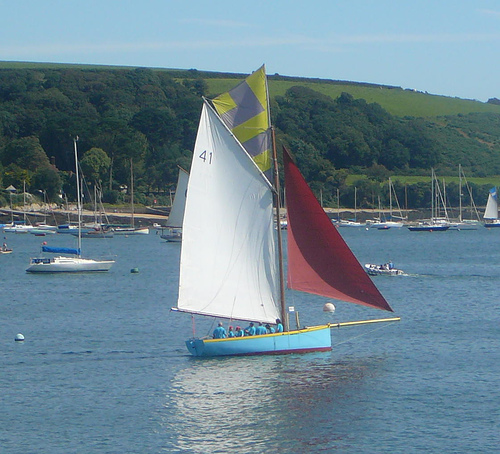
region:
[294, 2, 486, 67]
this is the sky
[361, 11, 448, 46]
the sky is blue in color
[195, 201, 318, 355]
this is a boat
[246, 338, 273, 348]
the boat is blue in color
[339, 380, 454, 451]
this is a water body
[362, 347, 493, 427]
the water is calm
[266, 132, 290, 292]
this is a pole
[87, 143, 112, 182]
this is a tree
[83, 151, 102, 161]
the leaves are green in color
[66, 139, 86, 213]
the pole is white in color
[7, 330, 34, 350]
small white buoy in water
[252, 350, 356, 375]
boat's blue reflection on water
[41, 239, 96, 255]
blue mast on boat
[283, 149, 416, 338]
red sail at end of boat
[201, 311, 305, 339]
people sitting in boat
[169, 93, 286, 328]
tall white mast on pole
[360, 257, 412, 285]
people in speed boat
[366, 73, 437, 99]
houses on the mountain top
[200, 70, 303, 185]
yellow and gray flag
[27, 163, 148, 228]
houses on the shore line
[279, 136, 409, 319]
A red sail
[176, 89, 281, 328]
A white sail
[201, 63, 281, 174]
A yellow and grey sail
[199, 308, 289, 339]
A group of people on a boat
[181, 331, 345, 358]
A blue boat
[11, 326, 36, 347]
A white bobber in the water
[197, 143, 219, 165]
The number 41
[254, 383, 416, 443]
Small ripples in the water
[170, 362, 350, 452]
The sailboat's reflection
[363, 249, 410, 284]
A small motorboat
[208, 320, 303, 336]
People in the boat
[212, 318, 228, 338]
This person has a blue shirt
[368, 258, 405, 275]
A small boat in the water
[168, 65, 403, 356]
A sailboat with people in it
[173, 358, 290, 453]
A reflection in the water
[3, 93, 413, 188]
Trees beyond the water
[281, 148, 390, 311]
A red sail on the boat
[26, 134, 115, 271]
A boat without the sail unfurled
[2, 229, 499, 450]
A body of water with boats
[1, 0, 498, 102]
Blue sky above the boats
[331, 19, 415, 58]
the sky is blue in color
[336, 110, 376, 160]
this is a tree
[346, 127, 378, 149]
the leaves are green in color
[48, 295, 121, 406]
the water is calm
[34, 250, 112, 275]
this is a boat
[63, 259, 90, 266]
the boat is white in color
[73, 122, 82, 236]
this is a pole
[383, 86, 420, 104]
this is a grass area